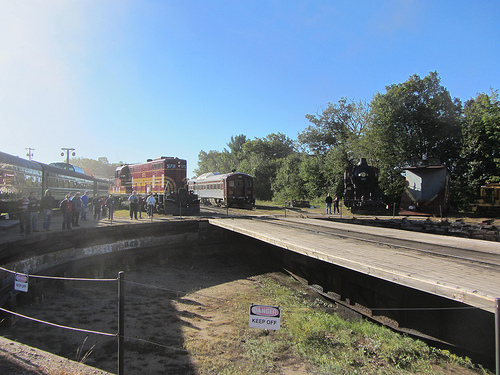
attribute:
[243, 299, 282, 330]
sign — danger, keep off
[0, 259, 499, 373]
fence — wire, protection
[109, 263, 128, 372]
fence post — made of metal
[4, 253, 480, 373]
grass — green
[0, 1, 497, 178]
sky — blue, clear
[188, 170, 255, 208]
train — red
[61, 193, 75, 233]
person — standing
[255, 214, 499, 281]
train tracks — dirty, grey, pictured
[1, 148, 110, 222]
train — black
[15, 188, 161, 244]
people — standing together, standing, looking at engine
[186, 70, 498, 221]
trees — green, adjacent to station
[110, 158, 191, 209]
train — heading out, red, long, sitting inactive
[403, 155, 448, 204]
building — blue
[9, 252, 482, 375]
area — roped off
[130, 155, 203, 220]
engine — large